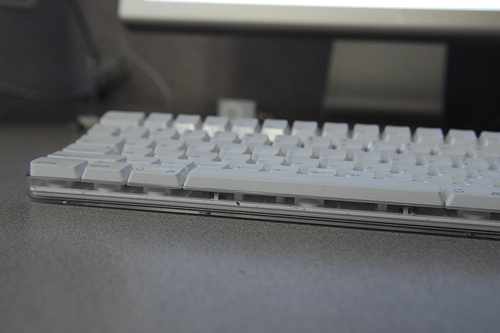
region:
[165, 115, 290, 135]
light shining on keyboard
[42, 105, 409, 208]
white computer keyboard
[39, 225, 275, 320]
grey table top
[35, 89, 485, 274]
white computer keyboard on top of grey table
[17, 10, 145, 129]
wires blurry behind computer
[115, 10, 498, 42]
white bottom of computer monitor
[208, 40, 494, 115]
Monitors black computer stand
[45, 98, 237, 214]
white keyboard with grey letters and numbers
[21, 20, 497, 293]
only computer on grey table no other items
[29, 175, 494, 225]
bottom of keyboard clear in color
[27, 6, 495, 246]
white keyboard under monitor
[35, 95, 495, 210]
individual raised keys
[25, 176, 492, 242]
bottom edge of support panel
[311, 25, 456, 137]
metal connector between keyboard and monitor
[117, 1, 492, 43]
dark edge below monitor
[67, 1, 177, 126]
wires behind table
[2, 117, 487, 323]
speckled gray surface of table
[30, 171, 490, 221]
round pads between spaces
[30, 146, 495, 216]
short and long bars on bottom row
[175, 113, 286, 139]
light reflecting off sides of keys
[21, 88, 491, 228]
white keyboard on desk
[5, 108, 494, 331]
desk keyboard is sitting on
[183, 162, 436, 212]
white space bar on keyboard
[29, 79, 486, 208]
raised white keys of keyboard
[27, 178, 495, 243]
bottom edge of keyboard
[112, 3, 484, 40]
bottom edge of computer screen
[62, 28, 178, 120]
white cords in background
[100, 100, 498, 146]
top row of keys on keyboard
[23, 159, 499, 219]
bottom row of keys on keyboard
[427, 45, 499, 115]
stand of computer screen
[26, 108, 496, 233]
white computer keyboard seen from table top leval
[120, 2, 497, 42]
bottom edge of monitor at top of picture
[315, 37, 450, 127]
stand holding monitor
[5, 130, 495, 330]
grey table or desk top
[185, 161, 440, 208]
long keyboard space bar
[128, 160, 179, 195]
keyboard alt key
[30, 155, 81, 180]
keyboard control key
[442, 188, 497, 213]
keyboard alt key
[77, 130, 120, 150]
keyboard tab key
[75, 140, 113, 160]
keyboard shift key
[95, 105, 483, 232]
white plastic button on keyboard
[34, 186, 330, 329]
gray surface under keyboard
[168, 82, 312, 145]
light shining down on keyboard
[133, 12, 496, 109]
silver monitor in backhground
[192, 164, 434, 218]
long white space bar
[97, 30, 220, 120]
blurry wires in back ground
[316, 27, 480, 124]
silver stand of monitor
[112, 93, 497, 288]
apple keyboard on counter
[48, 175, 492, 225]
bottom rim of keyboard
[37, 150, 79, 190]
white ctrl key on keyboard